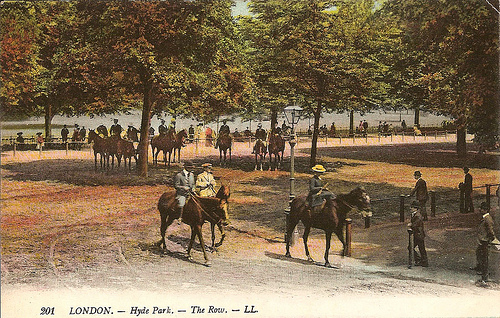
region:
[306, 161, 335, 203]
a woman riding side saddle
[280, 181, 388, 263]
a brown horse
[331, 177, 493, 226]
a wood fence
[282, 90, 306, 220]
a lamp post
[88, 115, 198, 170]
horses under a tree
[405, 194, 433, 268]
a man leaning on a post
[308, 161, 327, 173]
a yellow hat on a woman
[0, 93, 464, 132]
a body of water behind the trees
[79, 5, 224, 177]
a tree changing leaf color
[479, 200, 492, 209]
a black hat on a man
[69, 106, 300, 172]
a group of brown horses and riders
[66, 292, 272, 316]
the location in black type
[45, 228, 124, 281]
carriage tracks on the ground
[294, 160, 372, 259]
a woman in a hat on a brown horse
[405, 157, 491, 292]
four gentlemen watching the riders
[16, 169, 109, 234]
colorful patches of grass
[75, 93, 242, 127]
the water of a lake or river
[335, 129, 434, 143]
a series of wooden posts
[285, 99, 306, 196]
a black metal light post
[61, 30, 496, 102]
trees in multiple fall colors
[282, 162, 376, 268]
person in yellow hat sitting on a horse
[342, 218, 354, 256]
horse standing near a short wooden post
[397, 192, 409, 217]
person standing next to a brown fence post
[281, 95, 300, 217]
lamp post behind horse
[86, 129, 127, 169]
horse under tree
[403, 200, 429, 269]
man is standing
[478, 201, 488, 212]
black hat on man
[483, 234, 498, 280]
man leaning on a concrete wall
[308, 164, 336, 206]
person riding a horse sidesaddle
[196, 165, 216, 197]
person wearing a yellow jacket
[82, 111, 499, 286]
Victorian painting of a park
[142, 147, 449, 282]
Victorian painted brown horses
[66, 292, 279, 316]
London painting art black print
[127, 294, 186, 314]
Hyde Park print painting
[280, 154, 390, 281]
Victorian woman riding horse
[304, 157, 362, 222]
woman with a yellow sun hat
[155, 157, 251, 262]
two men with suits riding horses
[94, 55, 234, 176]
fall colored leaves on a tree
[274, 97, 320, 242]
Victorian style street light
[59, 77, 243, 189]
horses under the shadow of a tree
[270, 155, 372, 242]
a woman riding side saddle on a horse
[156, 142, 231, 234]
two men riding horses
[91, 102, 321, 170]
several people on horses under trees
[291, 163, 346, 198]
a woman wearing a yellow hat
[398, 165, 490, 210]
two men leaning on a fence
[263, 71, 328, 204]
a street lamp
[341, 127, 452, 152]
a fence with wooden post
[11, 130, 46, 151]
two women sitting on a bench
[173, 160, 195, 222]
a man wearing a suit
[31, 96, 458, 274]
several people in a park